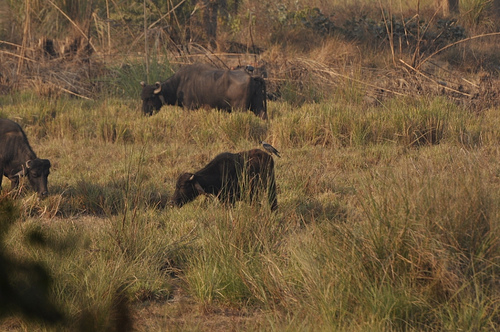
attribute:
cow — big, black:
[149, 54, 369, 139]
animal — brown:
[167, 148, 277, 213]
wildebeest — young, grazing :
[172, 149, 277, 213]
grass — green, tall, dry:
[11, 61, 496, 304]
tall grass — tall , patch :
[174, 107, 301, 310]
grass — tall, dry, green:
[98, 226, 488, 324]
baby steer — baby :
[172, 134, 285, 219]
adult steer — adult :
[170, 147, 280, 213]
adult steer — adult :
[2, 111, 52, 199]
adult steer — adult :
[139, 61, 268, 118]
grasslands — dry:
[1, 91, 495, 330]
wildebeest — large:
[0, 118, 52, 201]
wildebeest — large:
[169, 146, 277, 209]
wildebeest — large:
[138, 63, 268, 118]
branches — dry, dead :
[3, 2, 499, 127]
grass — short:
[332, 146, 394, 174]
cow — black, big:
[136, 62, 268, 120]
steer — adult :
[138, 60, 269, 122]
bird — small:
[260, 143, 279, 155]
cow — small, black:
[168, 147, 279, 212]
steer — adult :
[136, 57, 273, 121]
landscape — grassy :
[381, 98, 462, 147]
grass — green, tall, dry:
[0, 1, 499, 329]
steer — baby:
[154, 127, 289, 216]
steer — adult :
[5, 104, 59, 203]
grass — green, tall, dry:
[292, 89, 472, 148]